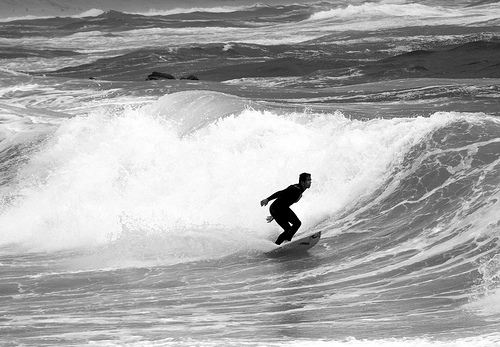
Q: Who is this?
A: Surfer.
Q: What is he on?
A: Surfboard.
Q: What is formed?
A: Waves.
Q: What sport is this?
A: Surfing.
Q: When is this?
A: Daytime.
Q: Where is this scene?
A: On a beach.